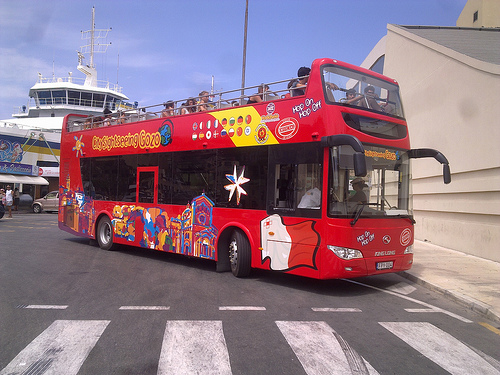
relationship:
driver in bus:
[346, 179, 367, 204] [8, 67, 400, 284]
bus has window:
[55, 55, 453, 282] [324, 141, 416, 224]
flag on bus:
[254, 211, 322, 277] [36, 69, 421, 270]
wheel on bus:
[219, 225, 253, 280] [55, 55, 453, 282]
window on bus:
[172, 145, 219, 212] [55, 55, 453, 282]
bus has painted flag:
[56, 53, 416, 279] [250, 205, 337, 275]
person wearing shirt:
[2, 181, 18, 218] [2, 187, 14, 204]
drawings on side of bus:
[109, 195, 219, 260] [56, 53, 416, 279]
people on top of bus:
[85, 63, 380, 127] [55, 55, 453, 282]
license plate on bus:
[375, 254, 395, 270] [56, 53, 416, 279]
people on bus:
[82, 65, 381, 127] [55, 55, 453, 282]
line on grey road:
[154, 314, 226, 374] [0, 212, 500, 373]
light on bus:
[330, 240, 359, 263] [56, 53, 416, 279]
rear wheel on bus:
[95, 213, 116, 248] [55, 55, 453, 282]